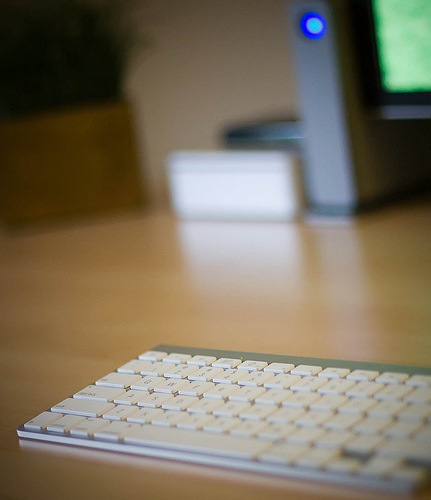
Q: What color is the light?
A: Blue.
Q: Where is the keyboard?
A: At the bottom of the photo.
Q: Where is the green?
A: On the monitor.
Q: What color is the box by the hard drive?
A: Silver.